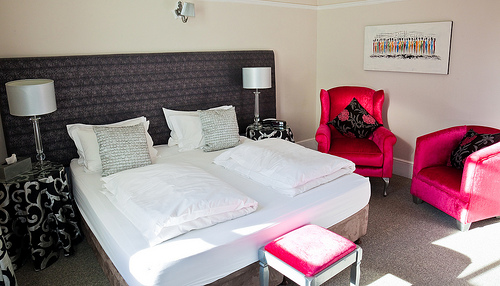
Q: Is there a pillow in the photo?
A: Yes, there is a pillow.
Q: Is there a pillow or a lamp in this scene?
A: Yes, there is a pillow.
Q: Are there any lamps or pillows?
A: Yes, there is a pillow.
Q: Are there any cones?
A: No, there are no cones.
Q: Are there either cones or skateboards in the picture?
A: No, there are no cones or skateboards.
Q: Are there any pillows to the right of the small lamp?
A: Yes, there is a pillow to the right of the lamp.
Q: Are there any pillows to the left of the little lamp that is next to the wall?
A: No, the pillow is to the right of the lamp.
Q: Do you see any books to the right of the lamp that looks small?
A: No, there is a pillow to the right of the lamp.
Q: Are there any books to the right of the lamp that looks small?
A: No, there is a pillow to the right of the lamp.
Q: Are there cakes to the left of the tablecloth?
A: No, there is a pillow to the left of the tablecloth.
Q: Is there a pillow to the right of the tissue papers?
A: Yes, there is a pillow to the right of the tissue papers.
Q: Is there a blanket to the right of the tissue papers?
A: No, there is a pillow to the right of the tissue papers.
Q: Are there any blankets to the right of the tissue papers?
A: No, there is a pillow to the right of the tissue papers.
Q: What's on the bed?
A: The pillow is on the bed.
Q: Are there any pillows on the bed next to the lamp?
A: Yes, there is a pillow on the bed.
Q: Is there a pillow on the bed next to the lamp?
A: Yes, there is a pillow on the bed.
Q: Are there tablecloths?
A: Yes, there is a tablecloth.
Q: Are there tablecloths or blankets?
A: Yes, there is a tablecloth.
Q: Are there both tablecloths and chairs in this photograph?
A: Yes, there are both a tablecloth and a chair.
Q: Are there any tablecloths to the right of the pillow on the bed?
A: Yes, there is a tablecloth to the right of the pillow.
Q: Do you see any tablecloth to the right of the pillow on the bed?
A: Yes, there is a tablecloth to the right of the pillow.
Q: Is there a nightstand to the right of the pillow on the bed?
A: No, there is a tablecloth to the right of the pillow.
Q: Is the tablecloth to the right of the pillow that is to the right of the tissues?
A: Yes, the tablecloth is to the right of the pillow.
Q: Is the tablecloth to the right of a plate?
A: No, the tablecloth is to the right of the pillow.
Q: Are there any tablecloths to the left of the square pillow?
A: Yes, there is a tablecloth to the left of the pillow.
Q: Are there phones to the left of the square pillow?
A: No, there is a tablecloth to the left of the pillow.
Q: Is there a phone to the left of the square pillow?
A: No, there is a tablecloth to the left of the pillow.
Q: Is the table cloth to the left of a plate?
A: No, the table cloth is to the left of the pillow.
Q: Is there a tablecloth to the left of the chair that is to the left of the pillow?
A: Yes, there is a tablecloth to the left of the chair.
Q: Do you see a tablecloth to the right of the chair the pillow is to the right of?
A: No, the tablecloth is to the left of the chair.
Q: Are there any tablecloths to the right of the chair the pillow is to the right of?
A: No, the tablecloth is to the left of the chair.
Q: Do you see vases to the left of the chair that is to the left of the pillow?
A: No, there is a tablecloth to the left of the chair.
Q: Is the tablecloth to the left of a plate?
A: No, the tablecloth is to the left of the chair.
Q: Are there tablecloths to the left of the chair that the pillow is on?
A: Yes, there is a tablecloth to the left of the chair.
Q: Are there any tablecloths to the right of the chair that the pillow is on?
A: No, the tablecloth is to the left of the chair.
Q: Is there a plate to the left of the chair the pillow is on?
A: No, there is a tablecloth to the left of the chair.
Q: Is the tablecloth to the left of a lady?
A: No, the tablecloth is to the left of the chair.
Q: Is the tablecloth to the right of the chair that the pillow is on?
A: No, the tablecloth is to the left of the chair.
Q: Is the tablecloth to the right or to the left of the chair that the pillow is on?
A: The tablecloth is to the left of the chair.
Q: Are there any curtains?
A: No, there are no curtains.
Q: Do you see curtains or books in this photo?
A: No, there are no curtains or books.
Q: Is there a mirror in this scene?
A: No, there are no mirrors.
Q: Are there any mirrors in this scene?
A: No, there are no mirrors.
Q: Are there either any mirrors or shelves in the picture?
A: No, there are no mirrors or shelves.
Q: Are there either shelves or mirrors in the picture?
A: No, there are no mirrors or shelves.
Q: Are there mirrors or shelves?
A: No, there are no shelves or mirrors.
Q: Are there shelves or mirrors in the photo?
A: No, there are no shelves or mirrors.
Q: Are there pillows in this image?
A: Yes, there is a pillow.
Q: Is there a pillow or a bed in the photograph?
A: Yes, there is a pillow.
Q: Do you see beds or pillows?
A: Yes, there is a pillow.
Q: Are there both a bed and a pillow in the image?
A: Yes, there are both a pillow and a bed.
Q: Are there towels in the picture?
A: No, there are no towels.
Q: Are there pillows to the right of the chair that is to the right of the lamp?
A: Yes, there is a pillow to the right of the chair.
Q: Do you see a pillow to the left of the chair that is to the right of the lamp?
A: No, the pillow is to the right of the chair.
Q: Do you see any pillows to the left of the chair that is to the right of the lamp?
A: No, the pillow is to the right of the chair.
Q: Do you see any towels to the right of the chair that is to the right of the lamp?
A: No, there is a pillow to the right of the chair.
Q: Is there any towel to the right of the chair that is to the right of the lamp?
A: No, there is a pillow to the right of the chair.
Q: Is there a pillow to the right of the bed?
A: Yes, there is a pillow to the right of the bed.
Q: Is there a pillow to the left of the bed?
A: No, the pillow is to the right of the bed.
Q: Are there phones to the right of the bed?
A: No, there is a pillow to the right of the bed.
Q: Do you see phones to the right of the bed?
A: No, there is a pillow to the right of the bed.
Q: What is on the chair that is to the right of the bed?
A: The pillow is on the chair.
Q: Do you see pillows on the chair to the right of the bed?
A: Yes, there is a pillow on the chair.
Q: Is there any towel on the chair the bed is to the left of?
A: No, there is a pillow on the chair.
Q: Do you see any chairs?
A: Yes, there is a chair.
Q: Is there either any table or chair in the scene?
A: Yes, there is a chair.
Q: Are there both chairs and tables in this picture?
A: Yes, there are both a chair and a table.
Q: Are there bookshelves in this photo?
A: No, there are no bookshelves.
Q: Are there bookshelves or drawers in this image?
A: No, there are no bookshelves or drawers.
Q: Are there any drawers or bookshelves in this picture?
A: No, there are no bookshelves or drawers.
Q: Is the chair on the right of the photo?
A: Yes, the chair is on the right of the image.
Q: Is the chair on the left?
A: No, the chair is on the right of the image.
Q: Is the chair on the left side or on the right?
A: The chair is on the right of the image.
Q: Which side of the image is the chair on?
A: The chair is on the right of the image.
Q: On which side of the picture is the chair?
A: The chair is on the right of the image.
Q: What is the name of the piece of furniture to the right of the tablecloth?
A: The piece of furniture is a chair.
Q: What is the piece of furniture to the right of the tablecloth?
A: The piece of furniture is a chair.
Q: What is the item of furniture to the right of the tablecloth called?
A: The piece of furniture is a chair.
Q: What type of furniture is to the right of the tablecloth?
A: The piece of furniture is a chair.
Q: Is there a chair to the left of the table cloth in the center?
A: No, the chair is to the right of the tablecloth.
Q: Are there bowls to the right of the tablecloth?
A: No, there is a chair to the right of the tablecloth.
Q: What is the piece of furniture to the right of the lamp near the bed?
A: The piece of furniture is a chair.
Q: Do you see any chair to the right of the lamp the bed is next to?
A: Yes, there is a chair to the right of the lamp.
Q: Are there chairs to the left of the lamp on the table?
A: No, the chair is to the right of the lamp.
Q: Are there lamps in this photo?
A: Yes, there is a lamp.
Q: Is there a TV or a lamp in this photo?
A: Yes, there is a lamp.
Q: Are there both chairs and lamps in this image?
A: Yes, there are both a lamp and a chair.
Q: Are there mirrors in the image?
A: No, there are no mirrors.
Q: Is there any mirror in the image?
A: No, there are no mirrors.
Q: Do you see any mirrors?
A: No, there are no mirrors.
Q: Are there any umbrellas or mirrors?
A: No, there are no mirrors or umbrellas.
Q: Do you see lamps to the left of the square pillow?
A: Yes, there is a lamp to the left of the pillow.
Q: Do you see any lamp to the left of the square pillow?
A: Yes, there is a lamp to the left of the pillow.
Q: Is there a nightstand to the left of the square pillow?
A: No, there is a lamp to the left of the pillow.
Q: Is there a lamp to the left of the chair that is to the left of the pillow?
A: Yes, there is a lamp to the left of the chair.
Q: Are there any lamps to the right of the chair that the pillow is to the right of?
A: No, the lamp is to the left of the chair.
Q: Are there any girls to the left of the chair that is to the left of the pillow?
A: No, there is a lamp to the left of the chair.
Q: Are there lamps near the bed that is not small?
A: Yes, there is a lamp near the bed.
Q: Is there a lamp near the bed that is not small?
A: Yes, there is a lamp near the bed.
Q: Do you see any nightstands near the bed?
A: No, there is a lamp near the bed.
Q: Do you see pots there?
A: No, there are no pots.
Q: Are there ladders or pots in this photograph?
A: No, there are no pots or ladders.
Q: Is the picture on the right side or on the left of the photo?
A: The picture is on the right of the image.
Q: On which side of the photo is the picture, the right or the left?
A: The picture is on the right of the image.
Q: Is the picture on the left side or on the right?
A: The picture is on the right of the image.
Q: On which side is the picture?
A: The picture is on the right of the image.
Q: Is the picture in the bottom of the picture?
A: No, the picture is in the top of the image.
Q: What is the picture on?
A: The picture is on the wall.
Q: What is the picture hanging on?
A: The picture is hanging on the wall.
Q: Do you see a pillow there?
A: Yes, there is a pillow.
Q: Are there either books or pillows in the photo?
A: Yes, there is a pillow.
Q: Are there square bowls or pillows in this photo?
A: Yes, there is a square pillow.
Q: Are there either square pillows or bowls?
A: Yes, there is a square pillow.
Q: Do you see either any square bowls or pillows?
A: Yes, there is a square pillow.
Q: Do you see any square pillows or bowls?
A: Yes, there is a square pillow.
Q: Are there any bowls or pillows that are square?
A: Yes, the pillow is square.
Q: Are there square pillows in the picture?
A: Yes, there is a square pillow.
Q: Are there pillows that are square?
A: Yes, there is a pillow that is square.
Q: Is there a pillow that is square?
A: Yes, there is a pillow that is square.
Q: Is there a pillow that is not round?
A: Yes, there is a square pillow.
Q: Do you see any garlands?
A: No, there are no garlands.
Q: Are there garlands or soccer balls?
A: No, there are no garlands or soccer balls.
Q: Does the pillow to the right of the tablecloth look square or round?
A: The pillow is square.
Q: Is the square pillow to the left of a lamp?
A: No, the pillow is to the right of a lamp.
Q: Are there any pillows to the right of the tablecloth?
A: Yes, there is a pillow to the right of the tablecloth.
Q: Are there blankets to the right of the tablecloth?
A: No, there is a pillow to the right of the tablecloth.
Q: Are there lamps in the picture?
A: Yes, there is a lamp.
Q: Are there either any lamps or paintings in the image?
A: Yes, there is a lamp.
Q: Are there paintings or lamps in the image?
A: Yes, there is a lamp.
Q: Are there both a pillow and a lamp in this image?
A: Yes, there are both a lamp and a pillow.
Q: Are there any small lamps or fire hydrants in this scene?
A: Yes, there is a small lamp.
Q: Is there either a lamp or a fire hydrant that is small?
A: Yes, the lamp is small.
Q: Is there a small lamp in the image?
A: Yes, there is a small lamp.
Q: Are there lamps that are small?
A: Yes, there is a lamp that is small.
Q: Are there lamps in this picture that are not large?
A: Yes, there is a small lamp.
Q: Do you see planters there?
A: No, there are no planters.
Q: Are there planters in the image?
A: No, there are no planters.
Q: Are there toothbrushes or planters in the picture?
A: No, there are no planters or toothbrushes.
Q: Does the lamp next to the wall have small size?
A: Yes, the lamp is small.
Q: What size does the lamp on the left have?
A: The lamp has small size.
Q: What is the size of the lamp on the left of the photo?
A: The lamp is small.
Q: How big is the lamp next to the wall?
A: The lamp is small.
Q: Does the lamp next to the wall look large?
A: No, the lamp is small.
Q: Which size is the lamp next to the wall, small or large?
A: The lamp is small.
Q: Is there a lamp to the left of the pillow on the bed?
A: Yes, there is a lamp to the left of the pillow.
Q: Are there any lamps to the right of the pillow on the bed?
A: No, the lamp is to the left of the pillow.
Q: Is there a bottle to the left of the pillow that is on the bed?
A: No, there is a lamp to the left of the pillow.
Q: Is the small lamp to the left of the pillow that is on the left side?
A: Yes, the lamp is to the left of the pillow.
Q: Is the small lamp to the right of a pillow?
A: No, the lamp is to the left of a pillow.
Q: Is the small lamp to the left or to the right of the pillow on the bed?
A: The lamp is to the left of the pillow.